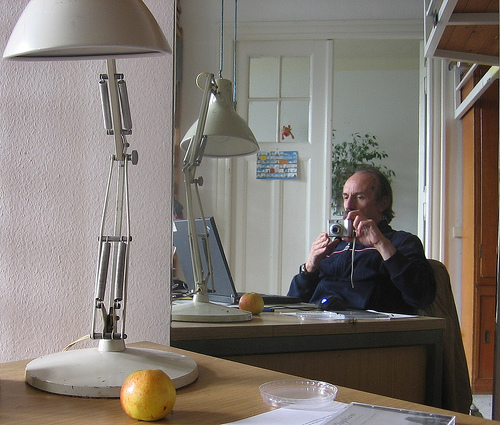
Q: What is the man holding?
A: A camera.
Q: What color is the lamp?
A: White.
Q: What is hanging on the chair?
A: Jacket.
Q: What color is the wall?
A: White.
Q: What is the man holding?
A: A camera.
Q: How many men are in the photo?
A: 1.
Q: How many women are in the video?
A: None.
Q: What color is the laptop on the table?
A: Black.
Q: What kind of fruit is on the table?
A: Apple.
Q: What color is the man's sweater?
A: Blue.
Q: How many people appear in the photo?
A: One.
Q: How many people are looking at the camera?
A: One.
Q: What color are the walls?
A: White.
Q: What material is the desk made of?
A: Wood.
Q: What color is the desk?
A: Tan.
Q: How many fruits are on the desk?
A: One.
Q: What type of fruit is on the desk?
A: Apple.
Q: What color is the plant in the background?
A: Green.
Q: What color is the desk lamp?
A: White.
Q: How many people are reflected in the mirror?
A: 1.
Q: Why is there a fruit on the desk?
A: To eat for a snack.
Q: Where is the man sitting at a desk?
A: Home office.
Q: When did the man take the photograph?
A: While working.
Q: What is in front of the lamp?
A: An apple.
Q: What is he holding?
A: A camera.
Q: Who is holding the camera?
A: The man.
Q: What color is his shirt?
A: Black.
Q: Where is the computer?
A: On the desk.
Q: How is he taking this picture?
A: Through a mirror.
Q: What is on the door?
A: A sign.